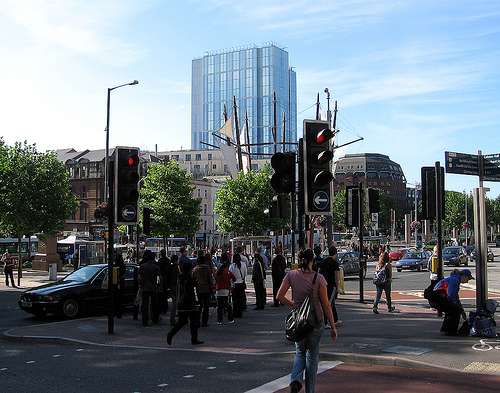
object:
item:
[468, 309, 498, 339]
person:
[2, 251, 19, 289]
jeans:
[287, 317, 326, 393]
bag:
[283, 271, 320, 343]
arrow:
[207, 94, 253, 181]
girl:
[272, 247, 340, 393]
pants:
[426, 286, 462, 336]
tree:
[0, 130, 83, 288]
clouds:
[25, 25, 99, 123]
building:
[330, 150, 423, 245]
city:
[0, 0, 500, 393]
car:
[469, 245, 495, 262]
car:
[441, 245, 469, 267]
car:
[395, 250, 431, 273]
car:
[331, 251, 369, 280]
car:
[17, 260, 171, 321]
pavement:
[0, 281, 500, 392]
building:
[187, 38, 304, 184]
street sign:
[440, 149, 500, 184]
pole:
[472, 184, 490, 315]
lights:
[125, 154, 139, 166]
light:
[315, 127, 328, 144]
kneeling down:
[425, 267, 476, 338]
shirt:
[282, 268, 329, 322]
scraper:
[187, 38, 302, 161]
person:
[372, 251, 397, 315]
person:
[165, 254, 206, 346]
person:
[213, 259, 237, 325]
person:
[227, 252, 248, 319]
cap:
[458, 268, 478, 281]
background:
[0, 60, 500, 240]